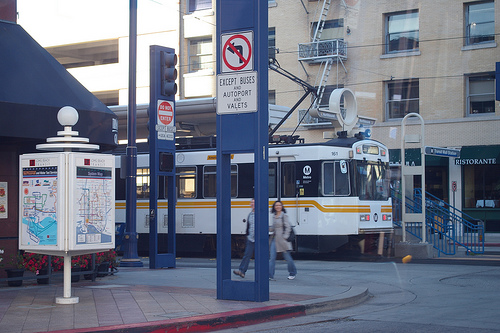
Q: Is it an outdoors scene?
A: Yes, it is outdoors.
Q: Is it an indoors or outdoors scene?
A: It is outdoors.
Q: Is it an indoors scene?
A: No, it is outdoors.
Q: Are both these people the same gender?
A: No, they are both male and female.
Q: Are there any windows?
A: Yes, there is a window.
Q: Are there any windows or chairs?
A: Yes, there is a window.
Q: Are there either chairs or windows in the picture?
A: Yes, there is a window.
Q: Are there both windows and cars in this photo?
A: No, there is a window but no cars.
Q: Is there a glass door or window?
A: Yes, there is a glass window.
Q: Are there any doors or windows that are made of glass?
A: Yes, the window is made of glass.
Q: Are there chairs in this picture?
A: No, there are no chairs.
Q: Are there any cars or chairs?
A: No, there are no chairs or cars.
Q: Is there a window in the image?
A: Yes, there is a window.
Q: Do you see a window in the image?
A: Yes, there is a window.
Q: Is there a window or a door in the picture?
A: Yes, there is a window.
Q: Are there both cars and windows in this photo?
A: No, there is a window but no cars.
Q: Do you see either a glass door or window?
A: Yes, there is a glass window.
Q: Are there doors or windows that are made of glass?
A: Yes, the window is made of glass.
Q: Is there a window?
A: Yes, there is a window.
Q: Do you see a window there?
A: Yes, there is a window.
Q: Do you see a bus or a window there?
A: Yes, there is a window.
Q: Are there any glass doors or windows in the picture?
A: Yes, there is a glass window.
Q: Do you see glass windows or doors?
A: Yes, there is a glass window.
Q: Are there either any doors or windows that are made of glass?
A: Yes, the window is made of glass.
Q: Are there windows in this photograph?
A: Yes, there is a window.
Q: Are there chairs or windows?
A: Yes, there is a window.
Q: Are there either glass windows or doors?
A: Yes, there is a glass window.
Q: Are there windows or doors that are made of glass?
A: Yes, the window is made of glass.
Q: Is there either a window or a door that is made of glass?
A: Yes, the window is made of glass.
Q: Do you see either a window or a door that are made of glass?
A: Yes, the window is made of glass.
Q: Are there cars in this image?
A: No, there are no cars.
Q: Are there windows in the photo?
A: Yes, there is a window.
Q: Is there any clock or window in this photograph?
A: Yes, there is a window.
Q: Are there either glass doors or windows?
A: Yes, there is a glass window.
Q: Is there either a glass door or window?
A: Yes, there is a glass window.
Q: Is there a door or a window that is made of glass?
A: Yes, the window is made of glass.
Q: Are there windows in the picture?
A: Yes, there is a window.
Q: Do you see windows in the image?
A: Yes, there is a window.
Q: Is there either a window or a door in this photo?
A: Yes, there is a window.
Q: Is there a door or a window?
A: Yes, there is a window.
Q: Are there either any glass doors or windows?
A: Yes, there is a glass window.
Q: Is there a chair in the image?
A: No, there are no chairs.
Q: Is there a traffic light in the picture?
A: Yes, there is a traffic light.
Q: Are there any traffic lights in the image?
A: Yes, there is a traffic light.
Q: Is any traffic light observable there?
A: Yes, there is a traffic light.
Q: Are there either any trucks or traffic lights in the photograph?
A: Yes, there is a traffic light.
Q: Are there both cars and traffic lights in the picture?
A: No, there is a traffic light but no cars.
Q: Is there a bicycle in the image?
A: No, there are no bicycles.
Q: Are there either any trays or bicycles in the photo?
A: No, there are no bicycles or trays.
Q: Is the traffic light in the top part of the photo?
A: Yes, the traffic light is in the top of the image.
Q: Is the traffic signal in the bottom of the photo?
A: No, the traffic signal is in the top of the image.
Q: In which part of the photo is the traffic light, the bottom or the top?
A: The traffic light is in the top of the image.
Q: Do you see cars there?
A: No, there are no cars.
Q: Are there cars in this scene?
A: No, there are no cars.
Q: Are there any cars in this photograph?
A: No, there are no cars.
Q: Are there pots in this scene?
A: No, there are no pots.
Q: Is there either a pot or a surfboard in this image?
A: No, there are no pots or surfboards.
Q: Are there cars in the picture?
A: No, there are no cars.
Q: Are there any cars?
A: No, there are no cars.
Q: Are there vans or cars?
A: No, there are no cars or vans.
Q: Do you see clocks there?
A: No, there are no clocks.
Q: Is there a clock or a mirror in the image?
A: No, there are no clocks or mirrors.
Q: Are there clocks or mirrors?
A: No, there are no clocks or mirrors.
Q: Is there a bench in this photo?
A: No, there are no benches.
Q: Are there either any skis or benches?
A: No, there are no benches or skis.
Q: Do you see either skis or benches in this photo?
A: No, there are no benches or skis.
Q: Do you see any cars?
A: No, there are no cars.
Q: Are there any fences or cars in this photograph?
A: No, there are no cars or fences.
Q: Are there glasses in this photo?
A: No, there are no glasses.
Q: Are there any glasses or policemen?
A: No, there are no glasses or policemen.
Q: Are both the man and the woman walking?
A: Yes, both the man and the woman are walking.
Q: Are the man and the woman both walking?
A: Yes, both the man and the woman are walking.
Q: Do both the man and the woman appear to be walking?
A: Yes, both the man and the woman are walking.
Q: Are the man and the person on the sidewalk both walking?
A: Yes, both the man and the woman are walking.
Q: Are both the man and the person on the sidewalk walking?
A: Yes, both the man and the woman are walking.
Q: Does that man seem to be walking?
A: Yes, the man is walking.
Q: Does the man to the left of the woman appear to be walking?
A: Yes, the man is walking.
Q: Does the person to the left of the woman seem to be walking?
A: Yes, the man is walking.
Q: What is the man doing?
A: The man is walking.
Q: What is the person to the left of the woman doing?
A: The man is walking.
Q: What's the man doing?
A: The man is walking.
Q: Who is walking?
A: The man is walking.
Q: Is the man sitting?
A: No, the man is walking.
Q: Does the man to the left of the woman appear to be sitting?
A: No, the man is walking.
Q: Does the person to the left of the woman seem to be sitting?
A: No, the man is walking.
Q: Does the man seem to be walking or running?
A: The man is walking.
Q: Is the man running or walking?
A: The man is walking.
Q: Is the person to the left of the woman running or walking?
A: The man is walking.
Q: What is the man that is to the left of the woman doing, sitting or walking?
A: The man is walking.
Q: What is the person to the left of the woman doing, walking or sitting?
A: The man is walking.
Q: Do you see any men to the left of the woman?
A: Yes, there is a man to the left of the woman.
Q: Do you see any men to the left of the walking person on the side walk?
A: Yes, there is a man to the left of the woman.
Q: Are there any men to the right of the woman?
A: No, the man is to the left of the woman.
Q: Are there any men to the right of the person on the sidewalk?
A: No, the man is to the left of the woman.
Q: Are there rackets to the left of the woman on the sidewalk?
A: No, there is a man to the left of the woman.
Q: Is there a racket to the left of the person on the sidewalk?
A: No, there is a man to the left of the woman.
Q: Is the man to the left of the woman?
A: Yes, the man is to the left of the woman.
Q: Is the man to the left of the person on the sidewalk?
A: Yes, the man is to the left of the woman.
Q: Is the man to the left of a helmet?
A: No, the man is to the left of the woman.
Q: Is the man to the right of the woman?
A: No, the man is to the left of the woman.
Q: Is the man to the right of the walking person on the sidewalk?
A: No, the man is to the left of the woman.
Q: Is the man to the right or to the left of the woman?
A: The man is to the left of the woman.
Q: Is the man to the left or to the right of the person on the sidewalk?
A: The man is to the left of the woman.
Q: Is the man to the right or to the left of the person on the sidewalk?
A: The man is to the left of the woman.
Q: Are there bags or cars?
A: No, there are no cars or bags.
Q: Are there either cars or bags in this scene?
A: No, there are no cars or bags.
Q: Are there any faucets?
A: No, there are no faucets.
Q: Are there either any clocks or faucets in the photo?
A: No, there are no faucets or clocks.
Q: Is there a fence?
A: No, there are no fences.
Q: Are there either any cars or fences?
A: No, there are no fences or cars.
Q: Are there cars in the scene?
A: No, there are no cars.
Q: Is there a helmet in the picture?
A: No, there are no helmets.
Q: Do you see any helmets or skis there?
A: No, there are no helmets or skis.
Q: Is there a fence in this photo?
A: No, there are no fences.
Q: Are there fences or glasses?
A: No, there are no fences or glasses.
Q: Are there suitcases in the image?
A: No, there are no suitcases.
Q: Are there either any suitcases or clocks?
A: No, there are no suitcases or clocks.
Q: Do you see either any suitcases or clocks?
A: No, there are no suitcases or clocks.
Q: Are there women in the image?
A: Yes, there is a woman.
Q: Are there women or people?
A: Yes, there is a woman.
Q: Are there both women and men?
A: Yes, there are both a woman and a man.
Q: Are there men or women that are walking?
A: Yes, the woman is walking.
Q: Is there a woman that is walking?
A: Yes, there is a woman that is walking.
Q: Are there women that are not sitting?
A: Yes, there is a woman that is walking.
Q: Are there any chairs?
A: No, there are no chairs.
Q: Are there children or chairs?
A: No, there are no chairs or children.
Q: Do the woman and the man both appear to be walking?
A: Yes, both the woman and the man are walking.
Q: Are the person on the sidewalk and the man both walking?
A: Yes, both the woman and the man are walking.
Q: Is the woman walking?
A: Yes, the woman is walking.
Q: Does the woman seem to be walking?
A: Yes, the woman is walking.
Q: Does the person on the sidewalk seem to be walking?
A: Yes, the woman is walking.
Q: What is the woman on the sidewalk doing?
A: The woman is walking.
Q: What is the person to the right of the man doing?
A: The woman is walking.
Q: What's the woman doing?
A: The woman is walking.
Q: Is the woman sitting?
A: No, the woman is walking.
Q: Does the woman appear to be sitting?
A: No, the woman is walking.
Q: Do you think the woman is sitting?
A: No, the woman is walking.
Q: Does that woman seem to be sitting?
A: No, the woman is walking.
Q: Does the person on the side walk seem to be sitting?
A: No, the woman is walking.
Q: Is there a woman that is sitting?
A: No, there is a woman but she is walking.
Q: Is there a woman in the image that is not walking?
A: No, there is a woman but she is walking.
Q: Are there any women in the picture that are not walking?
A: No, there is a woman but she is walking.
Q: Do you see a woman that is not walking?
A: No, there is a woman but she is walking.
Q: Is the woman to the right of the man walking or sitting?
A: The woman is walking.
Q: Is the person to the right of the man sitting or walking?
A: The woman is walking.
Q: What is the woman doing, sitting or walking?
A: The woman is walking.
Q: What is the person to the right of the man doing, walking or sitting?
A: The woman is walking.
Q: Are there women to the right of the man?
A: Yes, there is a woman to the right of the man.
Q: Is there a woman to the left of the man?
A: No, the woman is to the right of the man.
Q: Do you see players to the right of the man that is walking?
A: No, there is a woman to the right of the man.